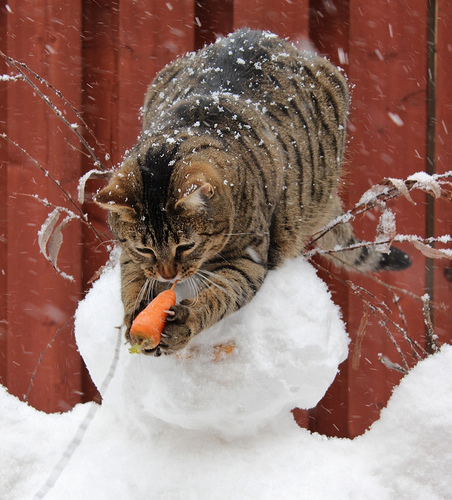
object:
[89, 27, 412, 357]
cat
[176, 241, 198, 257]
eye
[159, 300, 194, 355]
paw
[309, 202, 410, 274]
tail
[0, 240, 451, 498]
snowman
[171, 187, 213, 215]
ear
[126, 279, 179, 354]
carrot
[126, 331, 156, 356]
top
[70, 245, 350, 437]
snowball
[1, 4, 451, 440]
wall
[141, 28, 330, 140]
back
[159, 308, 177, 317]
claw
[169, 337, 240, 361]
mouth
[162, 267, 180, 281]
nose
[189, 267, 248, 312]
whiskers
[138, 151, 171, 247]
stripe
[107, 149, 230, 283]
head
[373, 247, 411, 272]
tip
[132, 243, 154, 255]
left eye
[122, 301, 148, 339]
left paw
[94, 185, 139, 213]
left ear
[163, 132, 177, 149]
snow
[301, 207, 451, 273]
branch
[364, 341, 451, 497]
arm